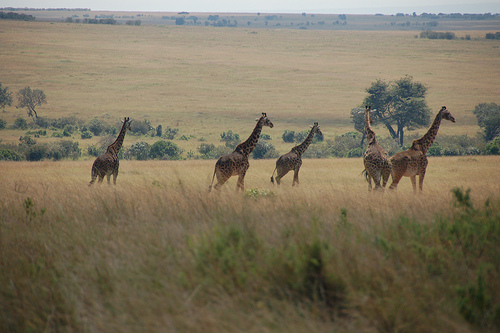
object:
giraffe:
[88, 116, 135, 185]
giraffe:
[214, 110, 273, 188]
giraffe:
[271, 121, 323, 187]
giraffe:
[363, 104, 393, 188]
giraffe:
[389, 105, 455, 190]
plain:
[1, 19, 499, 331]